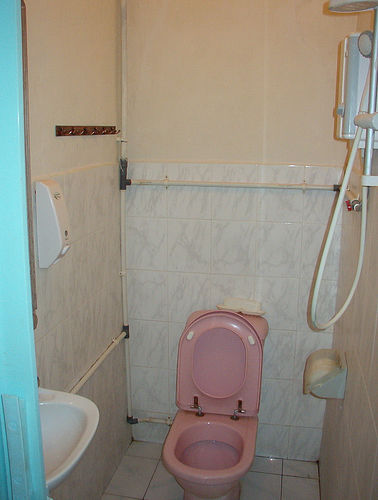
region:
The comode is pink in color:
[152, 302, 267, 495]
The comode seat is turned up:
[174, 312, 259, 419]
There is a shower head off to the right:
[354, 31, 375, 283]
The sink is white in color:
[40, 385, 102, 487]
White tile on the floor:
[130, 439, 168, 495]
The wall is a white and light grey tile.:
[125, 188, 337, 320]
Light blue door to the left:
[2, 252, 43, 499]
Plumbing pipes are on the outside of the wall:
[118, 157, 174, 428]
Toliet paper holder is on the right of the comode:
[300, 343, 350, 402]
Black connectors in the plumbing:
[121, 322, 130, 344]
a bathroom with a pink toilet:
[14, 3, 369, 493]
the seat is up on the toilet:
[175, 312, 262, 420]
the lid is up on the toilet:
[183, 309, 262, 415]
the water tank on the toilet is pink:
[184, 308, 267, 385]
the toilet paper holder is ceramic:
[299, 345, 349, 402]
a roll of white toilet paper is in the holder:
[308, 354, 337, 386]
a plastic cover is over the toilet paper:
[303, 344, 346, 398]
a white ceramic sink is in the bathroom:
[38, 383, 99, 494]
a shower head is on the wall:
[312, 0, 377, 332]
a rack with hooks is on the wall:
[53, 122, 121, 143]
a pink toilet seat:
[159, 308, 267, 498]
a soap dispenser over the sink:
[27, 174, 73, 275]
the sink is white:
[38, 380, 105, 498]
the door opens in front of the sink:
[0, 1, 48, 498]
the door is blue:
[0, 0, 48, 495]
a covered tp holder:
[300, 349, 352, 395]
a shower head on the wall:
[359, 23, 377, 181]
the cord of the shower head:
[299, 92, 367, 346]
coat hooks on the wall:
[45, 111, 120, 140]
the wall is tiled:
[119, 163, 338, 444]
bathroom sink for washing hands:
[36, 385, 101, 491]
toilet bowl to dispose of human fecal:
[164, 408, 253, 498]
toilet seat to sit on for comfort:
[176, 308, 254, 414]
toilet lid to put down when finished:
[196, 336, 240, 388]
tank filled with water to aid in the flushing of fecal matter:
[184, 307, 269, 337]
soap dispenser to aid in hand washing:
[33, 180, 70, 267]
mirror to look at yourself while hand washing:
[22, 1, 38, 330]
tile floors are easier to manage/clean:
[254, 454, 325, 498]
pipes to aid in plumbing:
[119, 0, 129, 422]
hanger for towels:
[55, 124, 121, 135]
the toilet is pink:
[148, 293, 279, 489]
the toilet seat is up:
[152, 307, 268, 483]